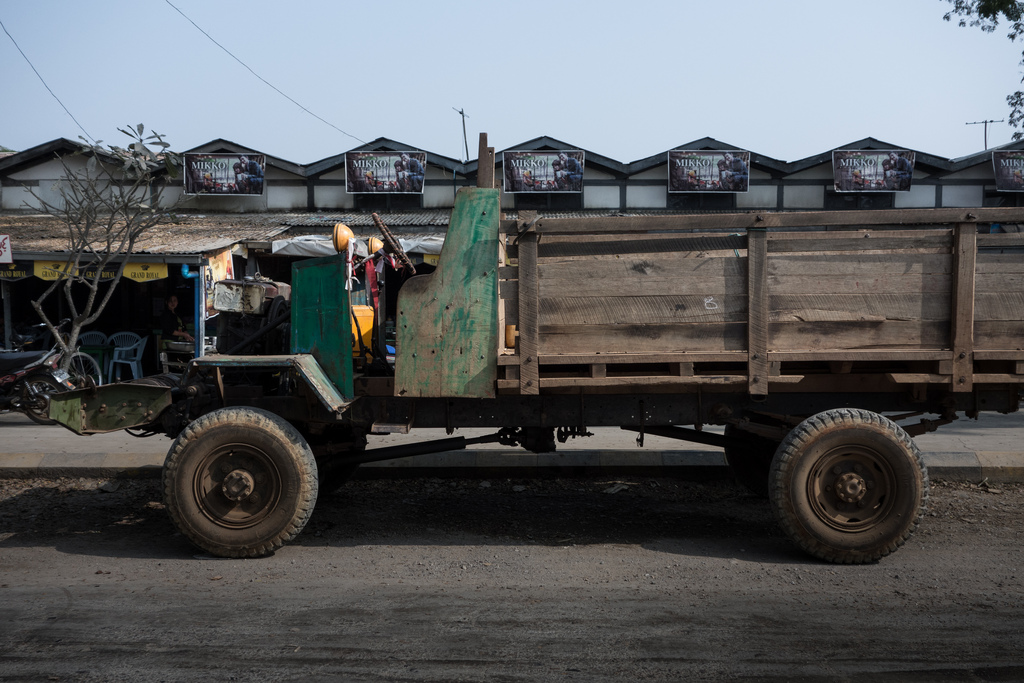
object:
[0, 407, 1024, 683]
road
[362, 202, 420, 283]
steering wheel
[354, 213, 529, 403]
door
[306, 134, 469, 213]
wall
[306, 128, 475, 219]
building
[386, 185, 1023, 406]
wood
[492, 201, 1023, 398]
truck bed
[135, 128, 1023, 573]
truck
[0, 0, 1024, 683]
outdoors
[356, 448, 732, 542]
shadow